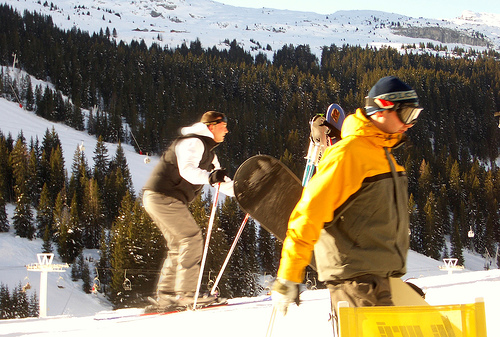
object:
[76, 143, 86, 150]
snow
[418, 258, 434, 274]
snow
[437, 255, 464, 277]
cross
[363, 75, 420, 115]
cap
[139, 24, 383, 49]
mountain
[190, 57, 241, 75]
trees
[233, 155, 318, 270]
ski board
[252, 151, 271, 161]
edge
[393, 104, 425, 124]
goggles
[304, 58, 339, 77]
trees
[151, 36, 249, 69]
valley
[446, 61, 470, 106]
trees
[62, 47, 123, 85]
forest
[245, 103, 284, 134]
forest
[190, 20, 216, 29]
snow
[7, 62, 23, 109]
ski lift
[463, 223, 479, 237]
cable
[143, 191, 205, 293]
pants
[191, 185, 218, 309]
poles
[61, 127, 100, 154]
slope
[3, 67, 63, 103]
hill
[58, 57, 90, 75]
trees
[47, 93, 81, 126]
rows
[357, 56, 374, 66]
fir trees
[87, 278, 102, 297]
carts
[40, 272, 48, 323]
pole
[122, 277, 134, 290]
lift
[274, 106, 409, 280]
jacket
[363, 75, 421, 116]
hat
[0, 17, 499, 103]
background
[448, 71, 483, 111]
forest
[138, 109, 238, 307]
man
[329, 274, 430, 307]
pants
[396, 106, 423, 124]
googles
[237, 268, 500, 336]
slope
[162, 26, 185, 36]
snow capped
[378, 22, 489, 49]
mountains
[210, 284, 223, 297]
chair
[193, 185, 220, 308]
ski pole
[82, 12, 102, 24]
snow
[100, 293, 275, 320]
ski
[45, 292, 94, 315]
ski slope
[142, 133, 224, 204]
black vest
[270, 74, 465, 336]
man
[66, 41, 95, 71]
forrest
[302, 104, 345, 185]
skies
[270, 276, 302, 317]
held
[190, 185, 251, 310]
set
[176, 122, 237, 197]
sweatshirt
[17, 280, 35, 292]
buggy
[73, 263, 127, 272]
support